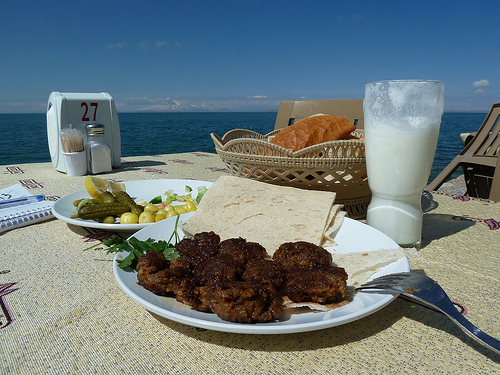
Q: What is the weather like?
A: It is clear.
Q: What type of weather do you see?
A: It is clear.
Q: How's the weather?
A: It is clear.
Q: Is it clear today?
A: Yes, it is clear.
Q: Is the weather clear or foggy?
A: It is clear.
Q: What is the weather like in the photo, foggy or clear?
A: It is clear.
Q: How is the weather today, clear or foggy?
A: It is clear.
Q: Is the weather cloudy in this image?
A: No, it is clear.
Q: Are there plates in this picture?
A: Yes, there is a plate.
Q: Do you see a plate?
A: Yes, there is a plate.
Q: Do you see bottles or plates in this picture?
A: Yes, there is a plate.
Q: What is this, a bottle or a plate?
A: This is a plate.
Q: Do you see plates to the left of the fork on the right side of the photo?
A: Yes, there is a plate to the left of the fork.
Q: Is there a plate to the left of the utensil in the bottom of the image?
A: Yes, there is a plate to the left of the fork.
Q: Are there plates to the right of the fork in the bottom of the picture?
A: No, the plate is to the left of the fork.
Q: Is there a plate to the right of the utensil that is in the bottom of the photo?
A: No, the plate is to the left of the fork.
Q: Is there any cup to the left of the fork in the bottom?
A: No, there is a plate to the left of the fork.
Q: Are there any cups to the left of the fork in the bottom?
A: No, there is a plate to the left of the fork.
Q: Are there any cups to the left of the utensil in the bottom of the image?
A: No, there is a plate to the left of the fork.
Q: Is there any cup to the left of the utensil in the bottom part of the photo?
A: No, there is a plate to the left of the fork.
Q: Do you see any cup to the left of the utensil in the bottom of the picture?
A: No, there is a plate to the left of the fork.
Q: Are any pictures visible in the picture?
A: No, there are no pictures.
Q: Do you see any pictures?
A: No, there are no pictures.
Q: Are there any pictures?
A: No, there are no pictures.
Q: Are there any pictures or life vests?
A: No, there are no pictures or life vests.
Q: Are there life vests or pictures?
A: No, there are no pictures or life vests.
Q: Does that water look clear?
A: Yes, the water is clear.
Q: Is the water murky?
A: No, the water is clear.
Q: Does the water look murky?
A: No, the water is clear.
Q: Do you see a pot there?
A: No, there are no pots.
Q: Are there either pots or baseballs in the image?
A: No, there are no pots or baseballs.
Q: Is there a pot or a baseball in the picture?
A: No, there are no pots or baseballs.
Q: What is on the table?
A: The glass is on the table.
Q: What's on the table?
A: The glass is on the table.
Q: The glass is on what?
A: The glass is on the table.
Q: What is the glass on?
A: The glass is on the table.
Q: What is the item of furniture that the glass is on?
A: The piece of furniture is a table.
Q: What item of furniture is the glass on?
A: The glass is on the table.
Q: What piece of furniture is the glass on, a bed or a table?
A: The glass is on a table.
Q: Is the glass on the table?
A: Yes, the glass is on the table.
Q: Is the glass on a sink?
A: No, the glass is on the table.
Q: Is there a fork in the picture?
A: Yes, there is a fork.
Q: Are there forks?
A: Yes, there is a fork.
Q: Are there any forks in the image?
A: Yes, there is a fork.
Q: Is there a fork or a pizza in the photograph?
A: Yes, there is a fork.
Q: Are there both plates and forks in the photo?
A: Yes, there are both a fork and a plate.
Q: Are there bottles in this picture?
A: No, there are no bottles.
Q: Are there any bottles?
A: No, there are no bottles.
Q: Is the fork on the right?
A: Yes, the fork is on the right of the image.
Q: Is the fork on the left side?
A: No, the fork is on the right of the image.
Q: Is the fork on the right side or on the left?
A: The fork is on the right of the image.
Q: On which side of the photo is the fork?
A: The fork is on the right of the image.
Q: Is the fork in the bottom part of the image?
A: Yes, the fork is in the bottom of the image.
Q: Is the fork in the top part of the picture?
A: No, the fork is in the bottom of the image.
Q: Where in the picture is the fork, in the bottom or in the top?
A: The fork is in the bottom of the image.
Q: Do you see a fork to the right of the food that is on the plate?
A: Yes, there is a fork to the right of the food.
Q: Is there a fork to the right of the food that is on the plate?
A: Yes, there is a fork to the right of the food.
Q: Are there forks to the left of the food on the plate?
A: No, the fork is to the right of the food.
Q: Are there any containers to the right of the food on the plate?
A: No, there is a fork to the right of the food.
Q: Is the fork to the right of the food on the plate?
A: Yes, the fork is to the right of the food.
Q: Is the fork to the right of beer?
A: No, the fork is to the right of the food.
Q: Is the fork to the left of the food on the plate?
A: No, the fork is to the right of the food.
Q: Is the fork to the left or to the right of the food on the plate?
A: The fork is to the right of the food.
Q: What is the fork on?
A: The fork is on the plate.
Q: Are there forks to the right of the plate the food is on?
A: Yes, there is a fork to the right of the plate.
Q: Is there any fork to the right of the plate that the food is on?
A: Yes, there is a fork to the right of the plate.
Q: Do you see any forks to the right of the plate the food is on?
A: Yes, there is a fork to the right of the plate.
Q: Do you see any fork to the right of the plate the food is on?
A: Yes, there is a fork to the right of the plate.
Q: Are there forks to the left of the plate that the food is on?
A: No, the fork is to the right of the plate.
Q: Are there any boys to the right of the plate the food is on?
A: No, there is a fork to the right of the plate.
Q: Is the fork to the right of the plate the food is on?
A: Yes, the fork is to the right of the plate.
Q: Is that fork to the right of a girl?
A: No, the fork is to the right of the plate.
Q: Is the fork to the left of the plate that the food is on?
A: No, the fork is to the right of the plate.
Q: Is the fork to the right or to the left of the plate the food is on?
A: The fork is to the right of the plate.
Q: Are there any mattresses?
A: No, there are no mattresses.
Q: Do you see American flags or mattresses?
A: No, there are no mattresses or American flags.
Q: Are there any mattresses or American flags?
A: No, there are no mattresses or American flags.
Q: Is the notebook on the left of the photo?
A: Yes, the notebook is on the left of the image.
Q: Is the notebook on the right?
A: No, the notebook is on the left of the image.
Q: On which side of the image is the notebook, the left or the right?
A: The notebook is on the left of the image.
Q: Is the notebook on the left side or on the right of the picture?
A: The notebook is on the left of the image.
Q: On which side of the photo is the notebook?
A: The notebook is on the left of the image.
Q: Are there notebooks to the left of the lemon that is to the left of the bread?
A: Yes, there is a notebook to the left of the lemon.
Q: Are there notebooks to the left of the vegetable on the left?
A: Yes, there is a notebook to the left of the lemon.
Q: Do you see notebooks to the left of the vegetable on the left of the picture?
A: Yes, there is a notebook to the left of the lemon.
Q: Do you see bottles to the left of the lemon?
A: No, there is a notebook to the left of the lemon.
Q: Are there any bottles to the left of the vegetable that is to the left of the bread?
A: No, there is a notebook to the left of the lemon.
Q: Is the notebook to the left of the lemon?
A: Yes, the notebook is to the left of the lemon.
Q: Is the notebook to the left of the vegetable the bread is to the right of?
A: Yes, the notebook is to the left of the lemon.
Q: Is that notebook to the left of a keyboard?
A: No, the notebook is to the left of the lemon.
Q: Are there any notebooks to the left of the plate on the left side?
A: Yes, there is a notebook to the left of the plate.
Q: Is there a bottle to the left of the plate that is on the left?
A: No, there is a notebook to the left of the plate.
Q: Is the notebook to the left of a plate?
A: Yes, the notebook is to the left of a plate.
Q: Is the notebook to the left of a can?
A: No, the notebook is to the left of a plate.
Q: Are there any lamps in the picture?
A: No, there are no lamps.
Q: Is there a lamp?
A: No, there are no lamps.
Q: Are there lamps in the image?
A: No, there are no lamps.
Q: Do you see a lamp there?
A: No, there are no lamps.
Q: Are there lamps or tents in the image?
A: No, there are no lamps or tents.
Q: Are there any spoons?
A: No, there are no spoons.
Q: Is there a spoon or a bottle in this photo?
A: No, there are no spoons or bottles.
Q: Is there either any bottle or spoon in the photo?
A: No, there are no spoons or bottles.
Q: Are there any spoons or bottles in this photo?
A: No, there are no spoons or bottles.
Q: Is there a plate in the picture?
A: Yes, there is a plate.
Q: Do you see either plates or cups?
A: Yes, there is a plate.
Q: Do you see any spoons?
A: No, there are no spoons.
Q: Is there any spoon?
A: No, there are no spoons.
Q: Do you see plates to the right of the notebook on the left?
A: Yes, there is a plate to the right of the notebook.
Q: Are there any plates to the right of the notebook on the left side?
A: Yes, there is a plate to the right of the notebook.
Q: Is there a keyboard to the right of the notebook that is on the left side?
A: No, there is a plate to the right of the notebook.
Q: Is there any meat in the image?
A: Yes, there is meat.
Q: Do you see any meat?
A: Yes, there is meat.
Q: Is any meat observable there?
A: Yes, there is meat.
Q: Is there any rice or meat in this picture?
A: Yes, there is meat.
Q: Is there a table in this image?
A: Yes, there is a table.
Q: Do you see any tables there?
A: Yes, there is a table.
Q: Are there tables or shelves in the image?
A: Yes, there is a table.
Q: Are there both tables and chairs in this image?
A: Yes, there are both a table and a chair.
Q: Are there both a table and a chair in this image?
A: Yes, there are both a table and a chair.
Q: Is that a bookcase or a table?
A: That is a table.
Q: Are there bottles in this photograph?
A: No, there are no bottles.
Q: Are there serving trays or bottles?
A: No, there are no bottles or serving trays.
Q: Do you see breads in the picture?
A: Yes, there is a bread.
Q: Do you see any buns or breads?
A: Yes, there is a bread.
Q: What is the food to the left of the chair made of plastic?
A: The food is a bread.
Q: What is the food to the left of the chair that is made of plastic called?
A: The food is a bread.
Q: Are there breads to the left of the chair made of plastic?
A: Yes, there is a bread to the left of the chair.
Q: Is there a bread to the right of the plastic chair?
A: No, the bread is to the left of the chair.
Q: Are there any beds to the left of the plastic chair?
A: No, there is a bread to the left of the chair.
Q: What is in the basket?
A: The bread is in the basket.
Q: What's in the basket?
A: The bread is in the basket.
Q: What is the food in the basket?
A: The food is a bread.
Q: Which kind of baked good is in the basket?
A: The food is a bread.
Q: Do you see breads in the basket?
A: Yes, there is a bread in the basket.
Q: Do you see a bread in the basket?
A: Yes, there is a bread in the basket.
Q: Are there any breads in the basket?
A: Yes, there is a bread in the basket.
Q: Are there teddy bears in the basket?
A: No, there is a bread in the basket.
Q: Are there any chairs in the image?
A: Yes, there is a chair.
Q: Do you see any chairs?
A: Yes, there is a chair.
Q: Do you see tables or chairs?
A: Yes, there is a chair.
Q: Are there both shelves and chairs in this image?
A: No, there is a chair but no shelves.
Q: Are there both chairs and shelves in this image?
A: No, there is a chair but no shelves.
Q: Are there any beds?
A: No, there are no beds.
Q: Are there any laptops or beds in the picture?
A: No, there are no beds or laptops.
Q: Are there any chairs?
A: Yes, there is a chair.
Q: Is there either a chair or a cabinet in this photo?
A: Yes, there is a chair.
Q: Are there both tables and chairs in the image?
A: Yes, there are both a chair and a table.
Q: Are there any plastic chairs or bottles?
A: Yes, there is a plastic chair.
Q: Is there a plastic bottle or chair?
A: Yes, there is a plastic chair.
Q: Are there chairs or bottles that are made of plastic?
A: Yes, the chair is made of plastic.